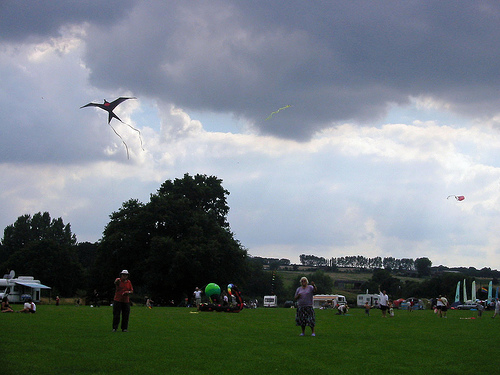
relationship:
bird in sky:
[80, 90, 130, 122] [5, 11, 495, 263]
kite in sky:
[69, 85, 167, 171] [5, 11, 495, 263]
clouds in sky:
[22, 0, 499, 165] [5, 11, 495, 263]